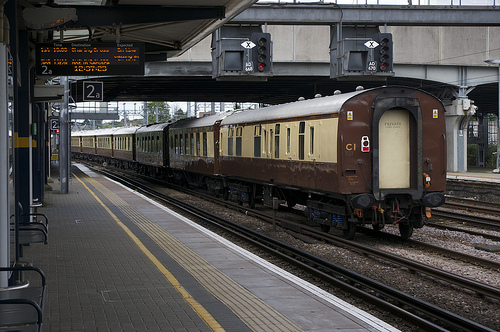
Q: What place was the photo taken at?
A: It was taken at the station.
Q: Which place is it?
A: It is a station.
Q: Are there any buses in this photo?
A: No, there are no buses.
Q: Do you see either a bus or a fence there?
A: No, there are no buses or fences.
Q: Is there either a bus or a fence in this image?
A: No, there are no buses or fences.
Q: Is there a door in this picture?
A: Yes, there is a door.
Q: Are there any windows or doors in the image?
A: Yes, there is a door.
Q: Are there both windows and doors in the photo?
A: Yes, there are both a door and a window.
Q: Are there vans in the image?
A: No, there are no vans.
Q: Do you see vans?
A: No, there are no vans.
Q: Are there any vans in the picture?
A: No, there are no vans.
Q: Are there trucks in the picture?
A: No, there are no trucks.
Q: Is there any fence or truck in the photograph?
A: No, there are no trucks or fences.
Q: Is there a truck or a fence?
A: No, there are no trucks or fences.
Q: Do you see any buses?
A: No, there are no buses.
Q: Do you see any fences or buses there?
A: No, there are no buses or fences.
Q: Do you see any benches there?
A: Yes, there is a bench.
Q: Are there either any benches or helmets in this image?
A: Yes, there is a bench.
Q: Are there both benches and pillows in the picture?
A: No, there is a bench but no pillows.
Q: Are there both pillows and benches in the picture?
A: No, there is a bench but no pillows.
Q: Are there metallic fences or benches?
A: Yes, there is a metal bench.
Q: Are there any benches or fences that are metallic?
A: Yes, the bench is metallic.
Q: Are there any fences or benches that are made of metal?
A: Yes, the bench is made of metal.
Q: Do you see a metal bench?
A: Yes, there is a metal bench.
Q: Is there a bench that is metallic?
A: Yes, there is a bench that is metallic.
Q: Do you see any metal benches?
A: Yes, there is a bench that is made of metal.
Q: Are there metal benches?
A: Yes, there is a bench that is made of metal.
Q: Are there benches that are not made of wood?
A: Yes, there is a bench that is made of metal.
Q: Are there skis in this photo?
A: No, there are no skis.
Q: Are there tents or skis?
A: No, there are no skis or tents.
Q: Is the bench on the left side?
A: Yes, the bench is on the left of the image.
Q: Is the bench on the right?
A: No, the bench is on the left of the image.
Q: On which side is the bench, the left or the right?
A: The bench is on the left of the image.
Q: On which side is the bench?
A: The bench is on the left of the image.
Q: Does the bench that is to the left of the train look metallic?
A: Yes, the bench is metallic.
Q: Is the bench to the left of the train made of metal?
A: Yes, the bench is made of metal.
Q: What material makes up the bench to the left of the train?
A: The bench is made of metal.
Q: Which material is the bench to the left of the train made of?
A: The bench is made of metal.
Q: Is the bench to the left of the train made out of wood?
A: No, the bench is made of metal.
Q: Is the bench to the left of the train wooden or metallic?
A: The bench is metallic.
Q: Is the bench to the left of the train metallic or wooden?
A: The bench is metallic.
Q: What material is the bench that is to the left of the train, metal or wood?
A: The bench is made of metal.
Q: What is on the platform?
A: The bench is on the platform.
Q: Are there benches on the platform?
A: Yes, there is a bench on the platform.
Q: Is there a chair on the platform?
A: No, there is a bench on the platform.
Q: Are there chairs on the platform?
A: No, there is a bench on the platform.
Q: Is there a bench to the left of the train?
A: Yes, there is a bench to the left of the train.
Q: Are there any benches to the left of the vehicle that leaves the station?
A: Yes, there is a bench to the left of the train.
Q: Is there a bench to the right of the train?
A: No, the bench is to the left of the train.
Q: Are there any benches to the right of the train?
A: No, the bench is to the left of the train.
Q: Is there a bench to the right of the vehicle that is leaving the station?
A: No, the bench is to the left of the train.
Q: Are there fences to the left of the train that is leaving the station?
A: No, there is a bench to the left of the train.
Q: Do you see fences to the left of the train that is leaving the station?
A: No, there is a bench to the left of the train.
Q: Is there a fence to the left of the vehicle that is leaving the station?
A: No, there is a bench to the left of the train.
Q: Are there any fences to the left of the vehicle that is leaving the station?
A: No, there is a bench to the left of the train.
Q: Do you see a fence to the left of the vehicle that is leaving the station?
A: No, there is a bench to the left of the train.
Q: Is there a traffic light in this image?
A: Yes, there is a traffic light.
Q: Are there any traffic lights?
A: Yes, there is a traffic light.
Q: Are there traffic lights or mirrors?
A: Yes, there is a traffic light.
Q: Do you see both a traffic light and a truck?
A: No, there is a traffic light but no trucks.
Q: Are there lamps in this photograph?
A: No, there are no lamps.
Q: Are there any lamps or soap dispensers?
A: No, there are no lamps or soap dispensers.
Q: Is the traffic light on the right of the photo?
A: Yes, the traffic light is on the right of the image.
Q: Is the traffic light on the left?
A: No, the traffic light is on the right of the image.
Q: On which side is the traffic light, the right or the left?
A: The traffic light is on the right of the image.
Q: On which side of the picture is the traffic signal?
A: The traffic signal is on the right of the image.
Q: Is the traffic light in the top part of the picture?
A: Yes, the traffic light is in the top of the image.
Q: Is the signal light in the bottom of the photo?
A: No, the signal light is in the top of the image.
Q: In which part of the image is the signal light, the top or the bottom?
A: The signal light is in the top of the image.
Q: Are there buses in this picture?
A: No, there are no buses.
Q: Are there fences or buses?
A: No, there are no buses or fences.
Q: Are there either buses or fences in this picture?
A: No, there are no buses or fences.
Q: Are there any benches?
A: Yes, there is a bench.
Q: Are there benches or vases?
A: Yes, there is a bench.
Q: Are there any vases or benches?
A: Yes, there is a bench.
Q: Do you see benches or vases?
A: Yes, there is a bench.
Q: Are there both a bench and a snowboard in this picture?
A: No, there is a bench but no snowboards.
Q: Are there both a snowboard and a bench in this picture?
A: No, there is a bench but no snowboards.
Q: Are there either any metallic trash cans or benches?
A: Yes, there is a metal bench.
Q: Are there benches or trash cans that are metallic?
A: Yes, the bench is metallic.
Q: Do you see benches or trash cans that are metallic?
A: Yes, the bench is metallic.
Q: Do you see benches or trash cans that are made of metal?
A: Yes, the bench is made of metal.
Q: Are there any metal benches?
A: Yes, there is a metal bench.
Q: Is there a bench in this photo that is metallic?
A: Yes, there is a bench that is metallic.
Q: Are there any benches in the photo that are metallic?
A: Yes, there is a bench that is metallic.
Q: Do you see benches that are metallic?
A: Yes, there is a bench that is metallic.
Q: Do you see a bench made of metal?
A: Yes, there is a bench that is made of metal.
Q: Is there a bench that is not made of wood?
A: Yes, there is a bench that is made of metal.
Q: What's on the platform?
A: The bench is on the platform.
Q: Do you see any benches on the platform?
A: Yes, there is a bench on the platform.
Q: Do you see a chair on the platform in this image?
A: No, there is a bench on the platform.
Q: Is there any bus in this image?
A: No, there are no buses.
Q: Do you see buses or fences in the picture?
A: No, there are no buses or fences.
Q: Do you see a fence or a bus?
A: No, there are no buses or fences.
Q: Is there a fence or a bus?
A: No, there are no buses or fences.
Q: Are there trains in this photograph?
A: Yes, there is a train.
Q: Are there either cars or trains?
A: Yes, there is a train.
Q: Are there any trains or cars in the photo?
A: Yes, there is a train.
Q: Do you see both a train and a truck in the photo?
A: No, there is a train but no trucks.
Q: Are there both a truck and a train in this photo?
A: No, there is a train but no trucks.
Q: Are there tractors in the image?
A: No, there are no tractors.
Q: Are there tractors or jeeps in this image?
A: No, there are no tractors or jeeps.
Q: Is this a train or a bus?
A: This is a train.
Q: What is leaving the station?
A: The train is leaving the station.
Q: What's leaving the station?
A: The train is leaving the station.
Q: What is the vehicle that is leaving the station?
A: The vehicle is a train.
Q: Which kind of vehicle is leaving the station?
A: The vehicle is a train.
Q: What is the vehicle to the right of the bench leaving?
A: The train is leaving the station.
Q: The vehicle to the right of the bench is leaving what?
A: The train is leaving the station.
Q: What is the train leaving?
A: The train is leaving the station.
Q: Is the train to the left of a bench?
A: No, the train is to the right of a bench.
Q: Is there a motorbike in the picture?
A: No, there are no motorcycles.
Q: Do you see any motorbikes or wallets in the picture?
A: No, there are no motorbikes or wallets.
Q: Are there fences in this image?
A: No, there are no fences.